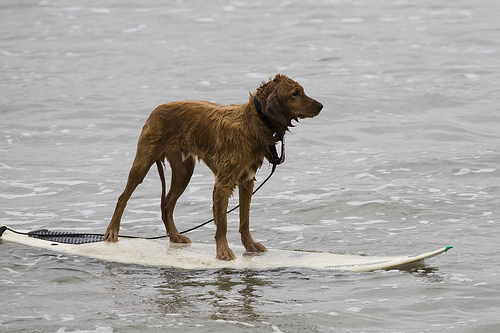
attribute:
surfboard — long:
[2, 221, 454, 273]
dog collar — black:
[250, 94, 286, 147]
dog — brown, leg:
[103, 70, 340, 261]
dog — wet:
[77, 62, 284, 267]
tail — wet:
[154, 160, 168, 204]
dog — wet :
[99, 67, 344, 284]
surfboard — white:
[8, 224, 452, 276]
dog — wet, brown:
[133, 77, 456, 204]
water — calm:
[1, 246, 496, 331]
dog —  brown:
[65, 65, 416, 297]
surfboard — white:
[72, 180, 494, 275]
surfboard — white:
[0, 228, 457, 273]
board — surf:
[0, 211, 465, 279]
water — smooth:
[4, 248, 154, 330]